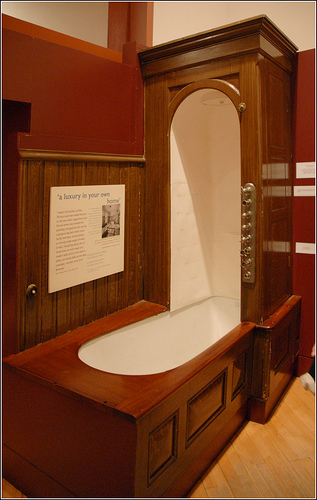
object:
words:
[50, 182, 121, 204]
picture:
[101, 199, 124, 238]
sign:
[48, 184, 130, 294]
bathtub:
[73, 305, 244, 375]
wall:
[0, 0, 150, 358]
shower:
[77, 66, 251, 375]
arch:
[163, 76, 249, 130]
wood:
[0, 1, 312, 499]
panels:
[144, 412, 179, 486]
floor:
[189, 375, 314, 498]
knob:
[26, 283, 40, 302]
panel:
[22, 153, 42, 351]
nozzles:
[238, 182, 255, 288]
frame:
[1, 13, 300, 491]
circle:
[197, 87, 235, 109]